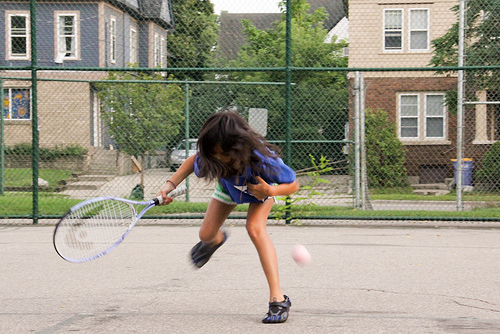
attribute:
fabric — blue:
[6, 84, 33, 120]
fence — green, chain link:
[0, 0, 499, 222]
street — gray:
[339, 213, 484, 332]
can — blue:
[428, 146, 498, 208]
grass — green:
[4, 190, 498, 218]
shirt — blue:
[253, 158, 281, 172]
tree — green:
[92, 66, 185, 166]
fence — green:
[274, 59, 437, 208]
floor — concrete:
[2, 223, 496, 331]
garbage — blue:
[422, 149, 489, 214]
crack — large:
[363, 282, 498, 312]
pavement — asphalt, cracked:
[1, 216, 498, 328]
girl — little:
[155, 103, 305, 329]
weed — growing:
[276, 153, 348, 224]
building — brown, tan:
[336, 23, 467, 140]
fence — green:
[322, 105, 449, 210]